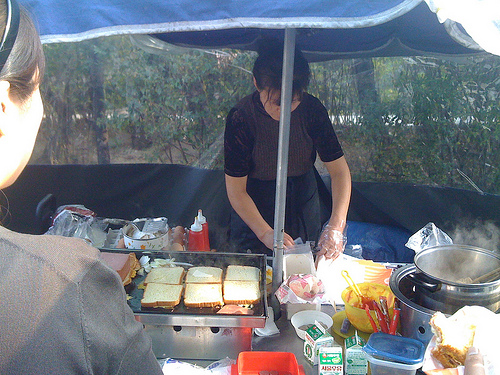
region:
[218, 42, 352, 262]
Woman with brown hair and gloves on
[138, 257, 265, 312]
6 sandwiches on a grill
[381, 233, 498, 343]
Steaming pots cooking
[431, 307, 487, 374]
Part of a sandwich with a bite taken out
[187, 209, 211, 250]
Two red and white ketchup bottles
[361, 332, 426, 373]
Tupperwear container with blue lid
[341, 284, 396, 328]
Small yellow bowl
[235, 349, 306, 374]
Red container sitting on table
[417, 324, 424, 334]
Hole in side of metal pot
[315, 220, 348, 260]
Clear glove on woman's hand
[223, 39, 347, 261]
this is an umbrella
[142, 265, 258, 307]
these are loaves of bread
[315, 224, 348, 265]
the woman is wearing a nylon glove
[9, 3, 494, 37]
this is an umbrella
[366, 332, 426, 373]
this is a tin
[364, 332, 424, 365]
the lid is blue in color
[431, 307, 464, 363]
the sandwich is bitten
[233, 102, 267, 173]
the blouse is black in color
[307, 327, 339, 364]
these are some milk packs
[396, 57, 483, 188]
these are tree branches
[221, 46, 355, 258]
A woman with black hair and gloves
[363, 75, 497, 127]
Green trees and vegetation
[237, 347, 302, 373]
An orange bowl on table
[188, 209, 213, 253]
Two red and white ketchup dispensers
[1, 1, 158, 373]
A woman with a hairband and gray shirt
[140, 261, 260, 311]
Six pieces of bread on a griddle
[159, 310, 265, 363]
A stainless steel griddle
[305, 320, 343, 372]
Two green and white containers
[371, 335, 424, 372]
Plastic container with a blue lid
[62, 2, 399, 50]
A blue tent with gray pole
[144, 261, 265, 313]
bread on a grill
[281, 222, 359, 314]
woman making food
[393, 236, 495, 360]
pots and pans to cook with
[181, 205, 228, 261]
plastic ketchup bottles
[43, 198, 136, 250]
old wrappers in the background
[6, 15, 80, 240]
customer waiting for her food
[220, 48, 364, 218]
woman behind pole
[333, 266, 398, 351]
condiments to put on sandwiches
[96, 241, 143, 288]
lunchmeat for sandwiches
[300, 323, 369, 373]
juices to drink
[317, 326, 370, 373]
two little green cardboard drink containers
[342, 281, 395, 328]
small yellow bowl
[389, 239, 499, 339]
set of steaming pots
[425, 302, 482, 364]
sandwich with a bite taken out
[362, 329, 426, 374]
small clear tupperwear with blue lid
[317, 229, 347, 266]
left hand with clear glove on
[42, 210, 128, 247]
piece of foil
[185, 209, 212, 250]
two bottles of ketchup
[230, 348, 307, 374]
red plastic container on table